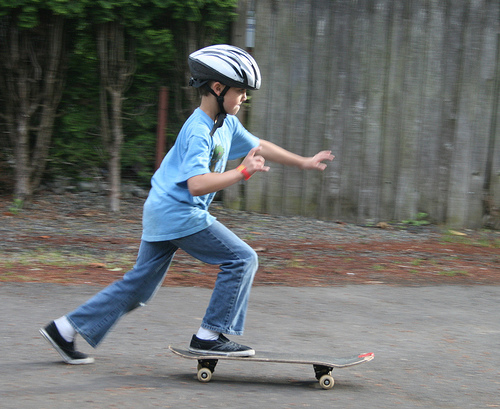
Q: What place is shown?
A: It is a pavement.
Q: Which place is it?
A: It is a pavement.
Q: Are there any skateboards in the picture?
A: Yes, there is a skateboard.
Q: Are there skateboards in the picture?
A: Yes, there is a skateboard.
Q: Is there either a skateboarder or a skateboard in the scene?
A: Yes, there is a skateboard.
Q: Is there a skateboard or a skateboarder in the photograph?
A: Yes, there is a skateboard.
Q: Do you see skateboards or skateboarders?
A: Yes, there is a skateboard.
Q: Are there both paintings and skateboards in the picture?
A: No, there is a skateboard but no paintings.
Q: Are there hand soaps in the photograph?
A: No, there are no hand soaps.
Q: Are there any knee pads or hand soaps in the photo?
A: No, there are no hand soaps or knee pads.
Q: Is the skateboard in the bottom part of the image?
A: Yes, the skateboard is in the bottom of the image.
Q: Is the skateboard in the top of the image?
A: No, the skateboard is in the bottom of the image.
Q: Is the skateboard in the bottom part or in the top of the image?
A: The skateboard is in the bottom of the image.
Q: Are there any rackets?
A: No, there are no rackets.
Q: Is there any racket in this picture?
A: No, there are no rackets.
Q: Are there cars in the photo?
A: No, there are no cars.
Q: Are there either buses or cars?
A: No, there are no cars or buses.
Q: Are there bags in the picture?
A: No, there are no bags.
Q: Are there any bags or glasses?
A: No, there are no bags or glasses.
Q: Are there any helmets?
A: Yes, there is a helmet.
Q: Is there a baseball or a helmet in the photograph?
A: Yes, there is a helmet.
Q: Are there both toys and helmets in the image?
A: No, there is a helmet but no toys.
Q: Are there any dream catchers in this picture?
A: No, there are no dream catchers.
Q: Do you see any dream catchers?
A: No, there are no dream catchers.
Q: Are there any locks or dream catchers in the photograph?
A: No, there are no dream catchers or locks.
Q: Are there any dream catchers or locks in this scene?
A: No, there are no dream catchers or locks.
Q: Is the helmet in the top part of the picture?
A: Yes, the helmet is in the top of the image.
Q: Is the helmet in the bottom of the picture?
A: No, the helmet is in the top of the image.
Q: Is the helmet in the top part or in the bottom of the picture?
A: The helmet is in the top of the image.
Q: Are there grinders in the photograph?
A: No, there are no grinders.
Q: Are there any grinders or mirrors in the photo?
A: No, there are no grinders or mirrors.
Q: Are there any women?
A: No, there are no women.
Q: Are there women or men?
A: No, there are no women or men.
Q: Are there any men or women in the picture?
A: No, there are no women or men.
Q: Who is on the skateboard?
A: The boy is on the skateboard.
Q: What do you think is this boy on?
A: The boy is on the skateboard.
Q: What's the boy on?
A: The boy is on the skateboard.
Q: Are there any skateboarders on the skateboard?
A: No, there is a boy on the skateboard.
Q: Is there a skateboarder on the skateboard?
A: No, there is a boy on the skateboard.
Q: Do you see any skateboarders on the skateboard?
A: No, there is a boy on the skateboard.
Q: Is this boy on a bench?
A: No, the boy is on the skateboard.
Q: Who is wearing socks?
A: The boy is wearing socks.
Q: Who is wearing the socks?
A: The boy is wearing socks.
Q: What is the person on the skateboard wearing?
A: The boy is wearing socks.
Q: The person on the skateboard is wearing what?
A: The boy is wearing socks.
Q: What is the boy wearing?
A: The boy is wearing socks.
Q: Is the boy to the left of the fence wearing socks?
A: Yes, the boy is wearing socks.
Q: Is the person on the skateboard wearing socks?
A: Yes, the boy is wearing socks.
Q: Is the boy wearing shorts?
A: No, the boy is wearing socks.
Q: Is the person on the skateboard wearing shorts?
A: No, the boy is wearing socks.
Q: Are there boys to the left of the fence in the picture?
A: Yes, there is a boy to the left of the fence.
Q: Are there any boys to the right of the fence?
A: No, the boy is to the left of the fence.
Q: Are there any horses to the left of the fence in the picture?
A: No, there is a boy to the left of the fence.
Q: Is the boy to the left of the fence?
A: Yes, the boy is to the left of the fence.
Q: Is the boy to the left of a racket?
A: No, the boy is to the left of the fence.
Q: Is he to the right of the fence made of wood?
A: No, the boy is to the left of the fence.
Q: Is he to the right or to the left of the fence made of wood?
A: The boy is to the left of the fence.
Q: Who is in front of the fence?
A: The boy is in front of the fence.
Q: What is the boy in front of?
A: The boy is in front of the fence.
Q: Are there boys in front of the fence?
A: Yes, there is a boy in front of the fence.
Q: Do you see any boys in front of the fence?
A: Yes, there is a boy in front of the fence.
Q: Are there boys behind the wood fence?
A: No, the boy is in front of the fence.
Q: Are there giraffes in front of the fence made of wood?
A: No, there is a boy in front of the fence.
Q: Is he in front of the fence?
A: Yes, the boy is in front of the fence.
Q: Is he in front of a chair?
A: No, the boy is in front of the fence.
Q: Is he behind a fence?
A: No, the boy is in front of a fence.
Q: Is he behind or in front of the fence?
A: The boy is in front of the fence.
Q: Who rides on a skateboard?
A: The boy rides on a skateboard.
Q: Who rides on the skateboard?
A: The boy rides on a skateboard.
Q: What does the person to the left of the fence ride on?
A: The boy rides on a skateboard.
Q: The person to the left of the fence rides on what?
A: The boy rides on a skateboard.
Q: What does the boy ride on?
A: The boy rides on a skateboard.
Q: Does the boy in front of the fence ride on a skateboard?
A: Yes, the boy rides on a skateboard.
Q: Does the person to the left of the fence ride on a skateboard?
A: Yes, the boy rides on a skateboard.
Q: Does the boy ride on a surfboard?
A: No, the boy rides on a skateboard.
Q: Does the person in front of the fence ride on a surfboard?
A: No, the boy rides on a skateboard.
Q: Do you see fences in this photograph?
A: Yes, there is a fence.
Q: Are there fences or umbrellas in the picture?
A: Yes, there is a fence.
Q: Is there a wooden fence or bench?
A: Yes, there is a wood fence.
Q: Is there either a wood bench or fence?
A: Yes, there is a wood fence.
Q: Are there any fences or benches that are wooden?
A: Yes, the fence is wooden.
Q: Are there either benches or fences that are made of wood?
A: Yes, the fence is made of wood.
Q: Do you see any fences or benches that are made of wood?
A: Yes, the fence is made of wood.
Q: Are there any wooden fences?
A: Yes, there is a wood fence.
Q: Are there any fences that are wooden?
A: Yes, there is a fence that is wooden.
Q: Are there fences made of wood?
A: Yes, there is a fence that is made of wood.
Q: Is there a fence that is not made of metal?
A: Yes, there is a fence that is made of wood.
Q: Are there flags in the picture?
A: No, there are no flags.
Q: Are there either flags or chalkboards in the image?
A: No, there are no flags or chalkboards.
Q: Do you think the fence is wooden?
A: Yes, the fence is wooden.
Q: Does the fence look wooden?
A: Yes, the fence is wooden.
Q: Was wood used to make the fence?
A: Yes, the fence is made of wood.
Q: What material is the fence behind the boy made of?
A: The fence is made of wood.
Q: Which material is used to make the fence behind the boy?
A: The fence is made of wood.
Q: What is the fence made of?
A: The fence is made of wood.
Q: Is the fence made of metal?
A: No, the fence is made of wood.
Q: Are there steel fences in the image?
A: No, there is a fence but it is made of wood.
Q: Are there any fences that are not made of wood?
A: No, there is a fence but it is made of wood.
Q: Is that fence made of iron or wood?
A: The fence is made of wood.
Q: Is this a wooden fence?
A: Yes, this is a wooden fence.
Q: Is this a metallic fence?
A: No, this is a wooden fence.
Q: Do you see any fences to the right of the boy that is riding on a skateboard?
A: Yes, there is a fence to the right of the boy.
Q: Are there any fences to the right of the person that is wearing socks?
A: Yes, there is a fence to the right of the boy.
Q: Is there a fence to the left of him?
A: No, the fence is to the right of the boy.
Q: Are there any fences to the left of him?
A: No, the fence is to the right of the boy.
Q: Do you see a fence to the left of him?
A: No, the fence is to the right of the boy.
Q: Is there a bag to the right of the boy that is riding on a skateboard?
A: No, there is a fence to the right of the boy.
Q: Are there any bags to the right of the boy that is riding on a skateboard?
A: No, there is a fence to the right of the boy.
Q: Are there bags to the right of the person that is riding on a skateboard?
A: No, there is a fence to the right of the boy.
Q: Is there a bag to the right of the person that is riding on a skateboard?
A: No, there is a fence to the right of the boy.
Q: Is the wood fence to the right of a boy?
A: Yes, the fence is to the right of a boy.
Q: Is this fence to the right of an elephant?
A: No, the fence is to the right of a boy.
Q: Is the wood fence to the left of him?
A: No, the fence is to the right of the boy.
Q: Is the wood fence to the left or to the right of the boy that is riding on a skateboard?
A: The fence is to the right of the boy.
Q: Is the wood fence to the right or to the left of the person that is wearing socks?
A: The fence is to the right of the boy.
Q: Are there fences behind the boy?
A: Yes, there is a fence behind the boy.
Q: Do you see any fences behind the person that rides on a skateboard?
A: Yes, there is a fence behind the boy.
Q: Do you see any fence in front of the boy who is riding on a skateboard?
A: No, the fence is behind the boy.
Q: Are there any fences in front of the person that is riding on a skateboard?
A: No, the fence is behind the boy.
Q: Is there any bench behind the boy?
A: No, there is a fence behind the boy.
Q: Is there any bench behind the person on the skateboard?
A: No, there is a fence behind the boy.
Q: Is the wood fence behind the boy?
A: Yes, the fence is behind the boy.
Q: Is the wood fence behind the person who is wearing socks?
A: Yes, the fence is behind the boy.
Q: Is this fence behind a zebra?
A: No, the fence is behind the boy.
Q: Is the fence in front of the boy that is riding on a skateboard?
A: No, the fence is behind the boy.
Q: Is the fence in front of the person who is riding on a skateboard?
A: No, the fence is behind the boy.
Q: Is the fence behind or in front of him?
A: The fence is behind the boy.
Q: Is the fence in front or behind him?
A: The fence is behind the boy.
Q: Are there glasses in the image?
A: No, there are no glasses.